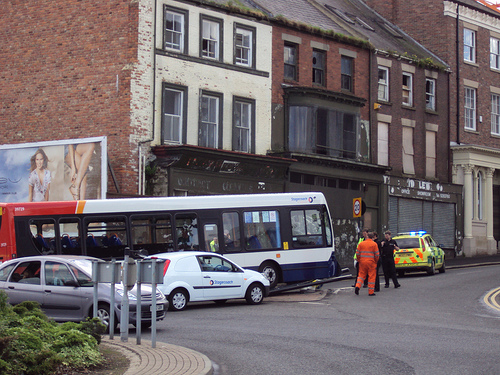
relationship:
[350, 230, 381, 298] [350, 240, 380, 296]
man wearing jumpsuit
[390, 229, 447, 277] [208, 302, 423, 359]
car parked on paving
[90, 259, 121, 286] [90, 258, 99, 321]
sign mounted on pole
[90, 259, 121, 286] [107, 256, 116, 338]
sign mounted on pole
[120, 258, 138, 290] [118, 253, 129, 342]
sign mounted on pole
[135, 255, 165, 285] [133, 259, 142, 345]
sign mounted on pole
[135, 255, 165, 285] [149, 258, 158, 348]
sign mounted on pole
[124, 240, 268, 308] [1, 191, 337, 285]
car crashed in bus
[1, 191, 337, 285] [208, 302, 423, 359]
bus crashed in paving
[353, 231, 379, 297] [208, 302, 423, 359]
man standing in paving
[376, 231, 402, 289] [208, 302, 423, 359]
man standing in paving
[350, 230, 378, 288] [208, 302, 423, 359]
man standing in paving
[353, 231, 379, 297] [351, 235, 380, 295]
man wearing jumpsuit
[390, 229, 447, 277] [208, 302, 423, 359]
car parked in paving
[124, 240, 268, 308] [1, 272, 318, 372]
car crashed in corner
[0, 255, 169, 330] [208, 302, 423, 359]
car driving on paving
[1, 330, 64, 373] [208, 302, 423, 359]
bush growing alongside paving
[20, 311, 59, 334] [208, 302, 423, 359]
bush growing alongside paving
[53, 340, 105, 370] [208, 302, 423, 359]
bush growing alongside paving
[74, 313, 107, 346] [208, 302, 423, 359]
bush growing alongside paving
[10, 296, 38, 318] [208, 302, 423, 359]
bush growing alongside paving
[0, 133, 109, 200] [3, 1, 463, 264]
billboard attached to building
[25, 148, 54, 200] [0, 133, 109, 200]
woman printed on billboard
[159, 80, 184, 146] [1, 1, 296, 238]
window adorning apartment building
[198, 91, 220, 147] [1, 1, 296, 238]
window adorning apartment building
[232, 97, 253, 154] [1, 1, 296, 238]
window adorning apartment building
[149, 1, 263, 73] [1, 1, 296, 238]
windows adorning apartment building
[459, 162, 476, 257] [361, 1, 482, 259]
pillar supporting building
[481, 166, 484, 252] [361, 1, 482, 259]
pillar supporting building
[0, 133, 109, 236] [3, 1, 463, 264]
billboard attached to building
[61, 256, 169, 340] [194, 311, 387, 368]
signs on street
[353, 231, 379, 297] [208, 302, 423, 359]
man on paving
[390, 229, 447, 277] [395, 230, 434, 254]
car with lights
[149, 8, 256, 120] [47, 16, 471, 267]
windows on building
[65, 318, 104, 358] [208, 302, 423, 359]
bush on paving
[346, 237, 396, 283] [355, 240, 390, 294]
man in jumpsuit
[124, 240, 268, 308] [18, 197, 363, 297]
car by bus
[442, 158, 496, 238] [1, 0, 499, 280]
columns on apartment building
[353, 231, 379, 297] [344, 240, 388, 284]
man in jumpsuit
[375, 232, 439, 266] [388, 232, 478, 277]
bar on vehicle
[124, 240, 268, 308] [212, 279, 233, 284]
car with lettering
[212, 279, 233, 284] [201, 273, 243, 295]
lettering on door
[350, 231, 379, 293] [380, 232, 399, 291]
man talking to man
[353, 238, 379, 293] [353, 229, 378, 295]
clothes on man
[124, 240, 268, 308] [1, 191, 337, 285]
car next to bus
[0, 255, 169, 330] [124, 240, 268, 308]
car next to car